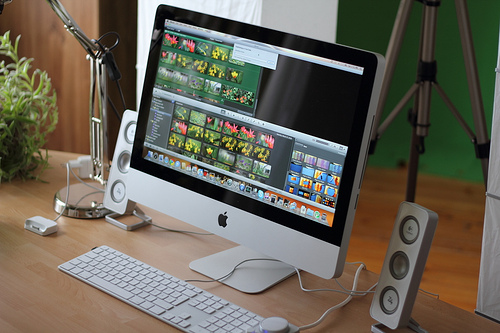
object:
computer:
[119, 2, 399, 281]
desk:
[2, 143, 497, 332]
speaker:
[367, 198, 444, 332]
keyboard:
[55, 240, 305, 333]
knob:
[257, 312, 289, 331]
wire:
[182, 253, 376, 302]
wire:
[54, 158, 75, 225]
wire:
[130, 206, 213, 250]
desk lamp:
[42, 0, 129, 226]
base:
[52, 180, 111, 220]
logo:
[217, 211, 230, 230]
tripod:
[364, 0, 492, 215]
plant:
[0, 25, 64, 185]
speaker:
[101, 102, 156, 218]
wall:
[336, 1, 500, 185]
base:
[405, 139, 424, 201]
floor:
[344, 163, 488, 327]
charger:
[22, 215, 60, 236]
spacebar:
[86, 271, 134, 300]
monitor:
[121, 2, 395, 291]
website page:
[135, 25, 351, 236]